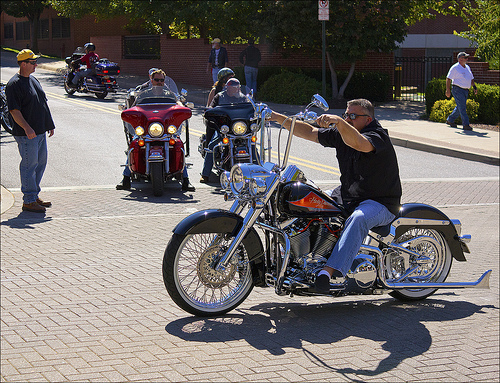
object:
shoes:
[313, 269, 333, 292]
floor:
[0, 62, 499, 383]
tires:
[160, 230, 257, 318]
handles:
[326, 122, 339, 130]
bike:
[160, 89, 491, 318]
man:
[264, 98, 404, 292]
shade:
[164, 291, 500, 382]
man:
[4, 47, 57, 213]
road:
[0, 62, 499, 382]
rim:
[171, 231, 254, 314]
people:
[115, 68, 196, 194]